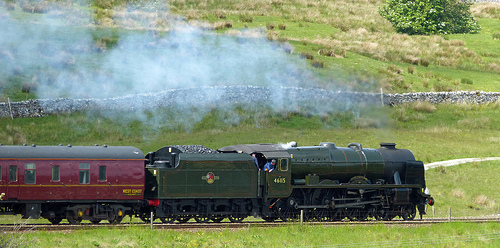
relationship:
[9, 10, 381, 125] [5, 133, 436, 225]
smoke coming from train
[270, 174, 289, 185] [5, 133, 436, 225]
numbers on train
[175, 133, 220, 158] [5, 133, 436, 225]
coal in train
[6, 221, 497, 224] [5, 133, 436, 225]
tracks under train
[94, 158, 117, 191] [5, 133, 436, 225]
window on train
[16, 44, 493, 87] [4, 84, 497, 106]
grass beside wall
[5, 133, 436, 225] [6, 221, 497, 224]
train on tracks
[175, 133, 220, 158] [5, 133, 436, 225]
coal on train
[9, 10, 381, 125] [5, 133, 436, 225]
smoke coming out train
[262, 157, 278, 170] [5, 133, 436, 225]
engineer of train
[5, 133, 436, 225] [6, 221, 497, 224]
train going down tracks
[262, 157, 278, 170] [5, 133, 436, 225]
man driving train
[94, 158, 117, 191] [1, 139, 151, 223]
window of train car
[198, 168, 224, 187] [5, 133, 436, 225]
logo of train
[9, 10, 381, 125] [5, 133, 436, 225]
smoke from train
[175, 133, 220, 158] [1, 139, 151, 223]
coal from train car